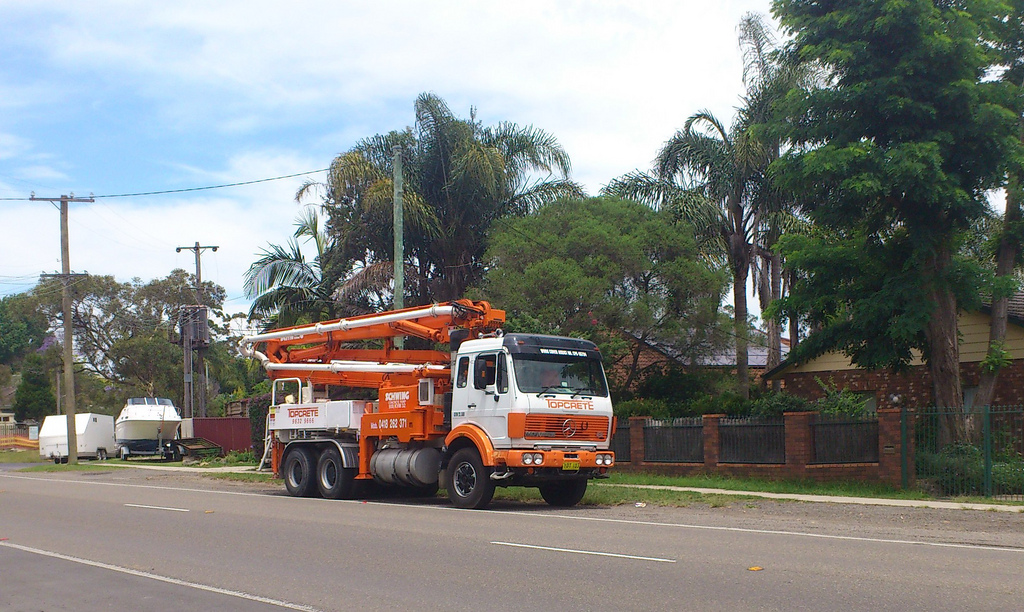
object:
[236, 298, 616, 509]
truck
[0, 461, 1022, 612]
street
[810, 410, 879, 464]
fence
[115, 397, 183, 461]
boat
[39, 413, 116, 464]
trailer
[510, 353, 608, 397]
windshield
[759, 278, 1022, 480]
houses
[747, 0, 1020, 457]
trees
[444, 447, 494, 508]
tires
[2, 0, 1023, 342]
sky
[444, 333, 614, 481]
cab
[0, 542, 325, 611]
lines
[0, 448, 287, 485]
lawn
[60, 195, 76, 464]
poles